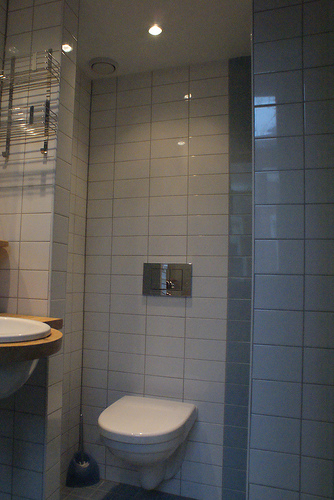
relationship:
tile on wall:
[253, 202, 306, 240] [245, 0, 332, 499]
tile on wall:
[184, 315, 226, 340] [78, 56, 252, 497]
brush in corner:
[66, 414, 101, 489] [70, 368, 105, 491]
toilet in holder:
[91, 388, 199, 490] [63, 446, 102, 488]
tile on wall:
[223, 53, 256, 498] [102, 92, 226, 234]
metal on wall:
[6, 55, 49, 141] [1, 2, 64, 321]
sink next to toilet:
[1, 302, 62, 400] [91, 388, 199, 490]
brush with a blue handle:
[66, 414, 101, 489] [76, 410, 87, 457]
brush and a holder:
[66, 414, 101, 489] [62, 448, 106, 485]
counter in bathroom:
[3, 296, 64, 355] [3, 2, 332, 491]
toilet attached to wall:
[96, 395, 198, 492] [126, 311, 209, 391]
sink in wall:
[3, 301, 69, 408] [3, 160, 86, 492]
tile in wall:
[148, 158, 188, 175] [96, 109, 219, 201]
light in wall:
[148, 24, 163, 37] [90, 80, 259, 476]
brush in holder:
[73, 412, 96, 481] [62, 448, 106, 485]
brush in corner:
[66, 414, 101, 489] [58, 67, 102, 490]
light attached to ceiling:
[145, 20, 163, 37] [74, 1, 251, 75]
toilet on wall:
[96, 395, 198, 492] [78, 56, 252, 497]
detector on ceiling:
[84, 56, 120, 77] [74, 1, 251, 75]